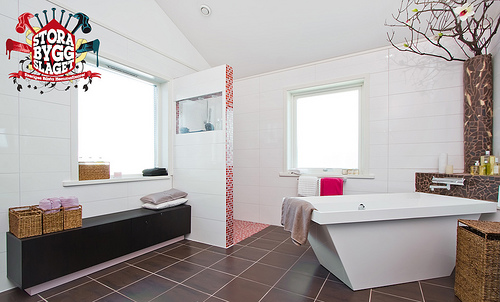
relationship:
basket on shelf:
[7, 205, 41, 239] [5, 202, 192, 289]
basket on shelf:
[41, 200, 60, 235] [5, 202, 192, 289]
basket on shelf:
[61, 203, 85, 230] [5, 202, 192, 289]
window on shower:
[173, 91, 222, 134] [171, 64, 270, 248]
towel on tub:
[280, 196, 316, 248] [298, 189, 498, 290]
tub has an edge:
[298, 189, 498, 290] [285, 192, 494, 228]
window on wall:
[283, 77, 366, 175] [232, 26, 499, 227]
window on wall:
[73, 54, 167, 180] [2, 1, 208, 288]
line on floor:
[84, 275, 135, 301] [0, 226, 458, 300]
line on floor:
[122, 260, 229, 301] [0, 226, 458, 300]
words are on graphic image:
[33, 30, 74, 75] [7, 7, 101, 95]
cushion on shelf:
[140, 186, 187, 205] [5, 202, 192, 289]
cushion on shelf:
[141, 199, 187, 211] [5, 202, 192, 289]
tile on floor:
[155, 259, 202, 283] [0, 226, 458, 300]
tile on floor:
[180, 267, 235, 295] [0, 226, 458, 300]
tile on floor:
[212, 276, 272, 300] [0, 226, 458, 300]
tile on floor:
[235, 262, 289, 286] [0, 226, 458, 300]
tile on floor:
[207, 255, 253, 277] [0, 226, 458, 300]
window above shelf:
[73, 54, 167, 180] [5, 202, 192, 289]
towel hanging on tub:
[280, 196, 316, 248] [298, 189, 498, 290]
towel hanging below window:
[298, 172, 320, 195] [283, 77, 366, 175]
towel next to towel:
[298, 172, 320, 195] [319, 175, 346, 197]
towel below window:
[319, 175, 346, 197] [283, 77, 366, 175]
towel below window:
[298, 172, 320, 195] [283, 77, 366, 175]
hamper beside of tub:
[453, 218, 499, 301] [298, 189, 498, 290]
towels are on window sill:
[142, 167, 168, 179] [60, 173, 168, 189]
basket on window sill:
[78, 162, 111, 180] [60, 173, 168, 189]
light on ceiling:
[198, 5, 212, 18] [151, 1, 498, 79]